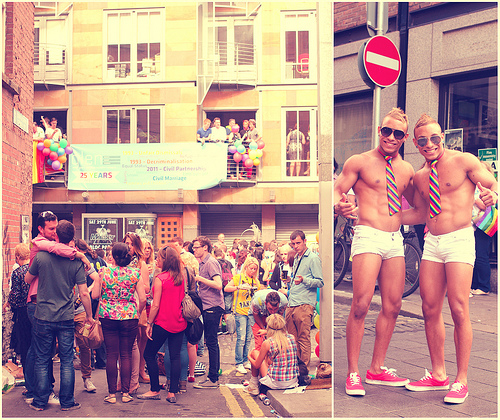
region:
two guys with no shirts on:
[341, 104, 498, 363]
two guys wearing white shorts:
[324, 100, 490, 295]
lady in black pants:
[147, 246, 219, 418]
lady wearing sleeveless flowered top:
[87, 237, 150, 407]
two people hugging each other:
[23, 211, 116, 412]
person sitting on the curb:
[196, 305, 311, 419]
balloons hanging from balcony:
[22, 92, 107, 216]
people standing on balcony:
[184, 97, 270, 248]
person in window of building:
[277, 94, 322, 196]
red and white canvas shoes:
[340, 362, 496, 417]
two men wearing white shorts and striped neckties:
[362, 106, 472, 408]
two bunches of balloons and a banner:
[36, 138, 262, 180]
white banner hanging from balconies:
[66, 143, 228, 186]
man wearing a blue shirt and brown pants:
[289, 230, 321, 365]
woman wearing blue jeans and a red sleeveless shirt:
[152, 243, 183, 398]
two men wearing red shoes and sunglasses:
[365, 107, 471, 404]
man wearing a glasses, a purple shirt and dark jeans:
[193, 237, 222, 383]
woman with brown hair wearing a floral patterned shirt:
[103, 240, 139, 406]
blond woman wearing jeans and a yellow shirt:
[236, 258, 252, 367]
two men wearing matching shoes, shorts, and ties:
[355, 108, 468, 402]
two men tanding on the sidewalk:
[344, 90, 496, 400]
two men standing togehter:
[298, 61, 499, 413]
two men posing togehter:
[304, 91, 487, 418]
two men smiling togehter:
[344, 76, 499, 384]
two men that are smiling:
[340, 91, 499, 393]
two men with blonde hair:
[330, 103, 497, 417]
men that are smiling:
[347, 69, 490, 415]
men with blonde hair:
[330, 98, 499, 298]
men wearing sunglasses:
[329, 55, 485, 307]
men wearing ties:
[365, 84, 499, 307]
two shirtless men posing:
[340, 115, 488, 403]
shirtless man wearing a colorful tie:
[412, 117, 489, 401]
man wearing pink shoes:
[407, 369, 474, 402]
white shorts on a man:
[422, 225, 474, 267]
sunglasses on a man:
[415, 136, 442, 148]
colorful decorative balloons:
[39, 140, 71, 170]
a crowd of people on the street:
[12, 212, 322, 394]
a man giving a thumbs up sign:
[475, 181, 495, 206]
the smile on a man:
[422, 145, 438, 155]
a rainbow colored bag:
[477, 210, 498, 235]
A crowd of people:
[4, 203, 324, 410]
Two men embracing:
[24, 208, 103, 410]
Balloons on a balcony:
[227, 138, 266, 174]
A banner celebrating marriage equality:
[67, 143, 228, 188]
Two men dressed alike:
[333, 105, 495, 407]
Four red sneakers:
[342, 367, 470, 407]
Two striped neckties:
[381, 154, 445, 219]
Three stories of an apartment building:
[38, 3, 322, 323]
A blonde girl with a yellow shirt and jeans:
[222, 255, 264, 375]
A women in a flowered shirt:
[90, 238, 142, 404]